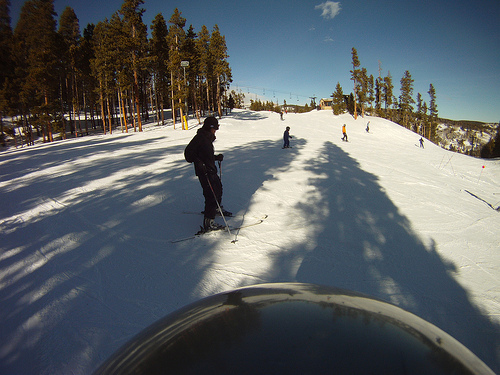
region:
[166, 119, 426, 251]
Skiers skiing on the mountain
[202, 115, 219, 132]
Black hat on top of skier's head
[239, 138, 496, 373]
Shadow of tree on the snow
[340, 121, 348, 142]
Person in orange coat in the distance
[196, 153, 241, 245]
Ski poles in skier's hands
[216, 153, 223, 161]
Black glove on skier's hand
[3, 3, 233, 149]
Trees in the snow behind skier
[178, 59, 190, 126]
Light on pole among the trees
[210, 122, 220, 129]
Black goggles on skier's face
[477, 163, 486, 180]
Red flag standing in the snow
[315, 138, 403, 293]
shadow of tree on snow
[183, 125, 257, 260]
person standing on skis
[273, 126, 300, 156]
small kid in snow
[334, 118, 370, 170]
person wearing orange sweater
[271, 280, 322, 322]
round front of snowmobile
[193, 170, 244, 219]
person wearing black pants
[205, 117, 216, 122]
person wearing black hat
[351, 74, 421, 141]
sparse grove of trees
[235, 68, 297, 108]
ski lift in distance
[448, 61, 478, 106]
bright vibrant blue sky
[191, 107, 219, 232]
that is a person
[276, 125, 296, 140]
that is a person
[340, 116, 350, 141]
that is a person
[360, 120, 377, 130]
that is a person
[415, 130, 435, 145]
that is a person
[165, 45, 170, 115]
that is a tree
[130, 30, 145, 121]
that is a tree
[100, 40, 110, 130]
that is a tree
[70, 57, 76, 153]
that is a tree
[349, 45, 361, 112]
that is a tree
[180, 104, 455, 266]
several skiers on a slope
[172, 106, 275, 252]
a person on snow skis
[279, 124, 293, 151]
a person on snow skis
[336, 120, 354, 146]
a person on snow skis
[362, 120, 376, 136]
a person on snow skis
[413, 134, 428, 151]
a person on snow skis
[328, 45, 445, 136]
several trees on a hillside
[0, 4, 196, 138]
several trees on a hillside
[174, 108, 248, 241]
a person wearing ski clothes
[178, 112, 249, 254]
a person holding two ski poles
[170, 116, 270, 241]
A skier standing with skis crossed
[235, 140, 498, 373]
Shadow of a tall tree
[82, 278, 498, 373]
helmet of the photographer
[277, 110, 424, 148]
several people skiing in the distance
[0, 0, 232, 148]
a group of trees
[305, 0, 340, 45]
a few small, wispy clouds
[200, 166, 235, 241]
a ski pole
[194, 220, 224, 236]
a ski boot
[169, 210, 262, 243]
a pair of skis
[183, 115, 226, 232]
a skier in warm clothing